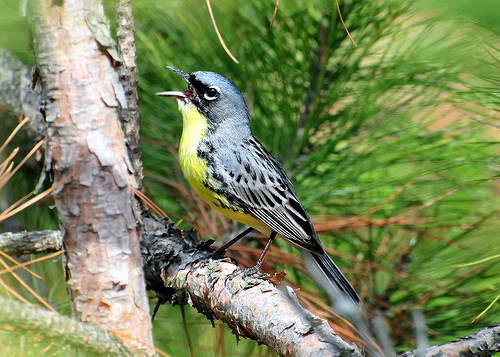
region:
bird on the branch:
[112, 49, 339, 265]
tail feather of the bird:
[269, 220, 376, 318]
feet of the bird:
[193, 230, 285, 291]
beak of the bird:
[136, 61, 195, 117]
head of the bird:
[150, 48, 265, 138]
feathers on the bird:
[226, 145, 294, 205]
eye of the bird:
[188, 80, 227, 126]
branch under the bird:
[169, 241, 277, 320]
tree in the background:
[332, 43, 412, 116]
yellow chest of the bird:
[173, 122, 208, 183]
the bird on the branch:
[133, 48, 366, 298]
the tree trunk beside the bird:
[33, 8, 145, 336]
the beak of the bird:
[156, 60, 191, 100]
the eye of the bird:
[205, 85, 224, 100]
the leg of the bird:
[225, 233, 284, 283]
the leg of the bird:
[183, 224, 258, 280]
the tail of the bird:
[301, 245, 383, 317]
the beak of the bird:
[138, 55, 198, 105]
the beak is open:
[157, 60, 194, 110]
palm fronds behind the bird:
[276, 17, 441, 175]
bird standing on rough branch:
[40, 16, 485, 341]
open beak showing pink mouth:
[150, 55, 240, 115]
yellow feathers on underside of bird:
[175, 100, 271, 245]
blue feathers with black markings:
[190, 62, 336, 252]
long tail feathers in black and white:
[302, 226, 362, 308]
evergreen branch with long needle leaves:
[260, 5, 490, 150]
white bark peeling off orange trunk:
[25, 1, 155, 351]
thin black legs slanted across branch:
[152, 205, 273, 305]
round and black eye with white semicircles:
[200, 80, 220, 100]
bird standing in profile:
[152, 48, 362, 319]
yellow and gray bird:
[150, 68, 305, 264]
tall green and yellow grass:
[371, 29, 448, 81]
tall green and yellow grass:
[382, 94, 486, 141]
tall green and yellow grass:
[368, 151, 450, 211]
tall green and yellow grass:
[438, 133, 493, 194]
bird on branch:
[154, 65, 309, 266]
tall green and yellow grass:
[16, 11, 66, 63]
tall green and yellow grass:
[138, 21, 180, 68]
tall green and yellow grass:
[147, 279, 185, 353]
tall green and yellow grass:
[414, 219, 483, 293]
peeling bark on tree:
[84, 14, 134, 188]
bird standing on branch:
[155, 65, 360, 292]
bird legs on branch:
[194, 227, 278, 291]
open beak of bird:
[157, 63, 193, 102]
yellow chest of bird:
[176, 105, 267, 235]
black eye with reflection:
[208, 88, 218, 97]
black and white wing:
[215, 139, 318, 249]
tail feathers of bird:
[305, 246, 358, 305]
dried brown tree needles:
[0, 115, 62, 303]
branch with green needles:
[147, 4, 497, 257]